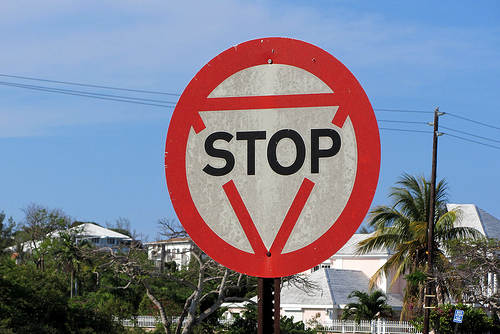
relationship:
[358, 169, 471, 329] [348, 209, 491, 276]
palm tree on background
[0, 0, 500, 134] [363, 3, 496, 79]
clouds on blue sky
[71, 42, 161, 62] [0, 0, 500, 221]
clouds in blue sky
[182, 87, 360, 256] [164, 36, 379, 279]
triangle on sign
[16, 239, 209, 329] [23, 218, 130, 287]
trees obscuring view of house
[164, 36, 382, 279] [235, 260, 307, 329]
sign with metal post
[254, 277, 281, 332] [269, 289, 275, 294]
metal with dot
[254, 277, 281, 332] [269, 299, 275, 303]
metal with dot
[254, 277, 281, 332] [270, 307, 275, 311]
metal with dot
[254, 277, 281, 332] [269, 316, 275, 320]
metal with dot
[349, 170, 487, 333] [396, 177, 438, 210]
palm tree with leaf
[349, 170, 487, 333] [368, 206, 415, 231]
palm tree with leaf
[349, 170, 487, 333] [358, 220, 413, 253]
palm tree with leaf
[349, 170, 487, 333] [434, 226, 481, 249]
palm tree with leaf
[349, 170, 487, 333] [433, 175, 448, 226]
palm tree with leaf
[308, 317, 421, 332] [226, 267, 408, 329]
fence by house